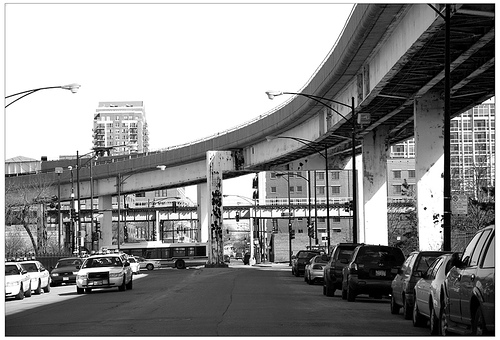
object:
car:
[388, 247, 451, 317]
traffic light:
[235, 208, 242, 222]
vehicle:
[341, 243, 404, 299]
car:
[18, 259, 53, 292]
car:
[51, 256, 88, 285]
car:
[291, 250, 322, 276]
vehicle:
[3, 262, 30, 297]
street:
[1, 267, 438, 334]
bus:
[115, 244, 214, 273]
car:
[322, 244, 385, 299]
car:
[304, 255, 330, 285]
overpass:
[0, 0, 500, 208]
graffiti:
[210, 169, 224, 266]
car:
[75, 253, 138, 294]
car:
[49, 258, 78, 286]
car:
[409, 249, 466, 331]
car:
[434, 223, 496, 337]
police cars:
[2, 262, 32, 297]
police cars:
[17, 260, 52, 293]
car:
[342, 245, 408, 302]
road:
[12, 238, 442, 335]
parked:
[437, 226, 492, 331]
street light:
[0, 81, 92, 108]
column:
[203, 148, 240, 268]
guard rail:
[217, 197, 356, 207]